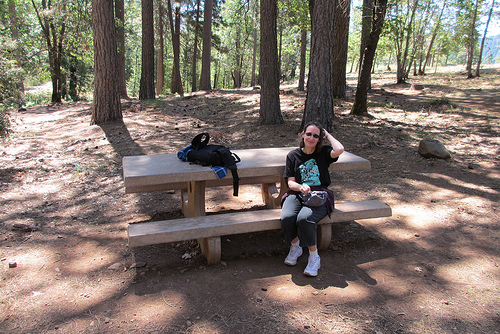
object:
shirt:
[283, 144, 339, 192]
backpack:
[177, 131, 244, 197]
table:
[121, 145, 373, 217]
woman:
[277, 121, 345, 277]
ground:
[0, 214, 124, 333]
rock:
[417, 138, 452, 160]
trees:
[90, 0, 123, 125]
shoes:
[303, 255, 323, 277]